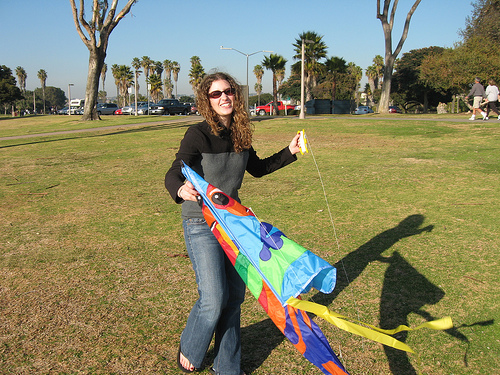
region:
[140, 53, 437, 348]
a woman holding a kite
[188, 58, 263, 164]
a woman with very curly hair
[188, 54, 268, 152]
a woman wearing sunglasses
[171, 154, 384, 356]
a brightly colored kite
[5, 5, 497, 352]
a large, grassy park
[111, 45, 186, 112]
palm trees and trucks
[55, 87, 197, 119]
a full parking lot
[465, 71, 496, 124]
a couple on a brisk walk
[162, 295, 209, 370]
sandals with flared jeans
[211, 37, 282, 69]
a light post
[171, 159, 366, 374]
a COLORFUL KITE.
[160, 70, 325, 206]
A young woman is holding a kite handle in her left hand.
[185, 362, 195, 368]
A female toe with red nail polish.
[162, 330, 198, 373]
A sandle on the female's right foot.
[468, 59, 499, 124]
An older couple walking along a path.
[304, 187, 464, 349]
A shadow made by the woman and the kite.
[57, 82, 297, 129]
A parking lot full of cars.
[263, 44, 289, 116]
A palm tree in the background.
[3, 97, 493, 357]
A park and recreation area.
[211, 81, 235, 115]
A woman smiles and squints in the sun.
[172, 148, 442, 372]
colorful kite with yellow tail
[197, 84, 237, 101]
ladies sunglasses with black frames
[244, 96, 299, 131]
red truck parked in parking lot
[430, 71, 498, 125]
two people walking in park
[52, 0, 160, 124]
tree with no leaves in the park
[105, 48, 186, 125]
palm trees lining a parking lot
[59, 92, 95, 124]
white camper truck at a distance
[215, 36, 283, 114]
light mounted to metal poles in parking lot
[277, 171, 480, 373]
shadow of lady holding kite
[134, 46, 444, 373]
ladies getting ready to fly kit in park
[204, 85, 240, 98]
sunglasses on woman with kite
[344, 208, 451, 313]
shadow of woman holding kite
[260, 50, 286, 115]
palm tree and red truck far behind woman with kite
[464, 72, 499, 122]
couple walking away from woman with kite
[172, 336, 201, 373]
foot of woman with kite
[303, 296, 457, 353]
yellow streamers on kite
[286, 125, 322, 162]
woman's hand holding string connected to kite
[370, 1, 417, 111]
tall tree without leaves behind woman with kite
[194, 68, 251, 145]
woman with long brown wavy hair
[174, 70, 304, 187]
woman in black and gray top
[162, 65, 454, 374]
A beautiful girl holding a flying kite.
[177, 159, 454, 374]
A really nice looking flying kite.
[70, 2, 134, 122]
A very tall trees with several branches.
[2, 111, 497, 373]
A very large brownish grass.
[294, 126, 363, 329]
The cord used to fly the kite.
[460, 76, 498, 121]
A young couple walking in the park.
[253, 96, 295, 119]
A red truck parked near the park.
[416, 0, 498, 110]
A very large tree with many leaves.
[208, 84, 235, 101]
A very nice pair of sunglasses.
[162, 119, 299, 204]
A nice sweater in the young woman's back.